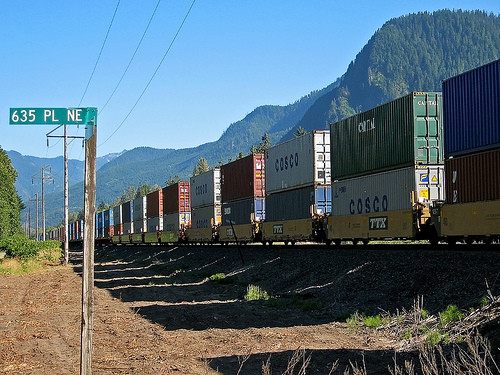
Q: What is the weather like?
A: It is clear.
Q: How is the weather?
A: It is clear.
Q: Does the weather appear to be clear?
A: Yes, it is clear.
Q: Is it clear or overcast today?
A: It is clear.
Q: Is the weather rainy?
A: No, it is clear.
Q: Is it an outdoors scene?
A: Yes, it is outdoors.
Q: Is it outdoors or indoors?
A: It is outdoors.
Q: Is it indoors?
A: No, it is outdoors.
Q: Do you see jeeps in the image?
A: No, there are no jeeps.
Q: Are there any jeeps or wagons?
A: No, there are no jeeps or wagons.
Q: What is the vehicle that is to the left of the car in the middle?
A: The vehicle is a train car.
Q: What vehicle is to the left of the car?
A: The vehicle is a train car.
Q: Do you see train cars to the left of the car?
A: Yes, there is a train car to the left of the car.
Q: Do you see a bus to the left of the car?
A: No, there is a train car to the left of the car.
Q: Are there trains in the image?
A: Yes, there is a train.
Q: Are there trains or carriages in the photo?
A: Yes, there is a train.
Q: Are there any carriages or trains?
A: Yes, there is a train.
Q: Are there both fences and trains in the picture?
A: No, there is a train but no fences.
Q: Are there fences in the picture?
A: No, there are no fences.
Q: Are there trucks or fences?
A: No, there are no fences or trucks.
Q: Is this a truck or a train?
A: This is a train.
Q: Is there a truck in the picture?
A: No, there are no trucks.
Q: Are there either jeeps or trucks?
A: No, there are no trucks or jeeps.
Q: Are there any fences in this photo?
A: No, there are no fences.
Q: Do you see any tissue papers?
A: No, there are no tissue papers.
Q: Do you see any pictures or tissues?
A: No, there are no tissues or pictures.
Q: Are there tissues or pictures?
A: No, there are no tissues or pictures.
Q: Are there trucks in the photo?
A: No, there are no trucks.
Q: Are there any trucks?
A: No, there are no trucks.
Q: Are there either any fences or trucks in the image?
A: No, there are no trucks or fences.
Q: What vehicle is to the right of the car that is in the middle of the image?
A: The vehicle is a train car.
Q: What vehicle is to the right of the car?
A: The vehicle is a train car.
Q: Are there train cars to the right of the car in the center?
A: Yes, there is a train car to the right of the car.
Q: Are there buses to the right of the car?
A: No, there is a train car to the right of the car.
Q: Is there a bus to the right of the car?
A: No, there is a train car to the right of the car.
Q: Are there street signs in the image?
A: Yes, there is a street sign.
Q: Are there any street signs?
A: Yes, there is a street sign.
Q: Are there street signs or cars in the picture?
A: Yes, there is a street sign.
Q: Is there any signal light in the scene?
A: No, there are no traffic lights.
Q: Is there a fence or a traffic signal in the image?
A: No, there are no traffic lights or fences.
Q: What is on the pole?
A: The street sign is on the pole.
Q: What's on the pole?
A: The street sign is on the pole.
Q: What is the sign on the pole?
A: The sign is a street sign.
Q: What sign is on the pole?
A: The sign is a street sign.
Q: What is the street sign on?
A: The street sign is on the pole.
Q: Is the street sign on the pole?
A: Yes, the street sign is on the pole.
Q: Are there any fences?
A: No, there are no fences.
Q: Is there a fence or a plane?
A: No, there are no fences or airplanes.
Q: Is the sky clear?
A: Yes, the sky is clear.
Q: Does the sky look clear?
A: Yes, the sky is clear.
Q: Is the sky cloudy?
A: No, the sky is clear.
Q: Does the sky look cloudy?
A: No, the sky is clear.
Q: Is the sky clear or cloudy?
A: The sky is clear.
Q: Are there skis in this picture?
A: No, there are no skis.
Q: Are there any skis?
A: No, there are no skis.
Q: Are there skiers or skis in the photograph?
A: No, there are no skis or skiers.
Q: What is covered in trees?
A: The mountain is covered in trees.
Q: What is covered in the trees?
A: The mountain is covered in trees.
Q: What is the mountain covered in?
A: The mountain is covered in trees.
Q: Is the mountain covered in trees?
A: Yes, the mountain is covered in trees.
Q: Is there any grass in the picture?
A: Yes, there is grass.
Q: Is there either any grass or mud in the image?
A: Yes, there is grass.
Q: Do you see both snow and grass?
A: No, there is grass but no snow.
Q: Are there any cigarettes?
A: No, there are no cigarettes.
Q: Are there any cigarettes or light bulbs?
A: No, there are no cigarettes or light bulbs.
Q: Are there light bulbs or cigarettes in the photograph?
A: No, there are no cigarettes or light bulbs.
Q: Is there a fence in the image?
A: No, there are no fences.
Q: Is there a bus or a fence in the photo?
A: No, there are no fences or buses.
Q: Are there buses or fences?
A: No, there are no fences or buses.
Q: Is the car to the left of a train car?
A: Yes, the car is to the left of a train car.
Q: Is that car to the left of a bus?
A: No, the car is to the left of a train car.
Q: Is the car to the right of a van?
A: No, the car is to the right of a train car.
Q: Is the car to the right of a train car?
A: Yes, the car is to the right of a train car.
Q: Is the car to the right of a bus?
A: No, the car is to the right of a train car.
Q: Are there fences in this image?
A: No, there are no fences.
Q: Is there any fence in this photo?
A: No, there are no fences.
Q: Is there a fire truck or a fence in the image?
A: No, there are no fences or fire trucks.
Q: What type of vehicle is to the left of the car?
A: The vehicle is a train car.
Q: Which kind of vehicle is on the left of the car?
A: The vehicle is a train car.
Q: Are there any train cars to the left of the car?
A: Yes, there is a train car to the left of the car.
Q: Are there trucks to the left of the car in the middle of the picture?
A: No, there is a train car to the left of the car.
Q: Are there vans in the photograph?
A: No, there are no vans.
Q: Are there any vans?
A: No, there are no vans.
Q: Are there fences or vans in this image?
A: No, there are no vans or fences.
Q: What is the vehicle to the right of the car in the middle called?
A: The vehicle is a train car.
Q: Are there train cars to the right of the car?
A: Yes, there is a train car to the right of the car.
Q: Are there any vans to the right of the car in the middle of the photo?
A: No, there is a train car to the right of the car.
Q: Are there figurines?
A: No, there are no figurines.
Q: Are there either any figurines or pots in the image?
A: No, there are no figurines or pots.